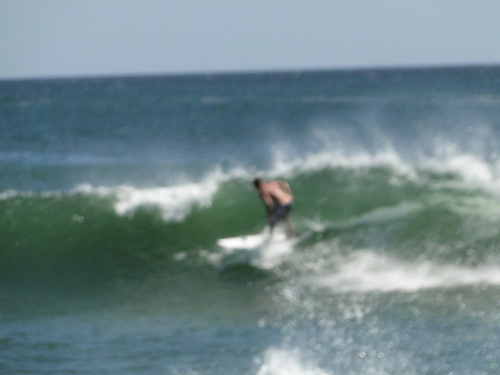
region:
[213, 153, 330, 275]
blurry photo of a surfer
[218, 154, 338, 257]
person in the water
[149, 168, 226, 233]
whit water next to surfer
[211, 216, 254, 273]
white board of the surfer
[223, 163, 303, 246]
person not wearing a shirt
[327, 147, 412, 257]
big wave in the water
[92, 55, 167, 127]
still water in the background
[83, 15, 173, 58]
blue sky above water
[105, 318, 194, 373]
water in the foreground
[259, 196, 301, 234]
shorts of the person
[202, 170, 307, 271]
a surfer riding a wave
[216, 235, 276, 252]
a white surf board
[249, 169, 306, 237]
a man on a surf board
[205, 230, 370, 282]
splash of water from surf board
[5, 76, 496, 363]
the ocean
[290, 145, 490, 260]
a wave crashing down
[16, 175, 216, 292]
wave beginning to crest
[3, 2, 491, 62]
a clear, blue sky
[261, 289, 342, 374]
reflection of light in the water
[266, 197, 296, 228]
swim trunks on the man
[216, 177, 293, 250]
a man riding a wave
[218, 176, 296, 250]
a man riding on a surf board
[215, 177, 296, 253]
a man surfing in the ocean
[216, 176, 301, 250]
a man in the ocean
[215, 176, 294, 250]
a man surfing an ocean wave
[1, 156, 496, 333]
a big blue ocean wave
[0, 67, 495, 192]
clear blue ocean in background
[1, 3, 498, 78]
clear blue sky in background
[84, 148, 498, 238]
top of wave curling over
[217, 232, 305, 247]
white surf board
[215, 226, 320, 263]
white surf board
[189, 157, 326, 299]
man riding white surf board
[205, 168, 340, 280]
surfer on white surfboard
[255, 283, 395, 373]
ocean water splashing in air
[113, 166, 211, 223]
white sea foam on top of wave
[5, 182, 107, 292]
large wave on water surface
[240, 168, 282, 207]
man with dark hair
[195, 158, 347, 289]
man balancing on surfboard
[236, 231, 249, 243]
black design on white surfboard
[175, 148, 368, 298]
shirtless man riding surfboard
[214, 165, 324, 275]
man riding surfboard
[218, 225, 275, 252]
white surfboard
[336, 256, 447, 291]
white foam on top of wave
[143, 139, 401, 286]
surfer riding large wave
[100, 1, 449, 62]
clear sky with no clouds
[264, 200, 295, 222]
black blurry swim trunks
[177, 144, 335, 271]
shirtless man on surf board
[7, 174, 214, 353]
large wave on top of water surface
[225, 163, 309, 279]
man with dark brown hair